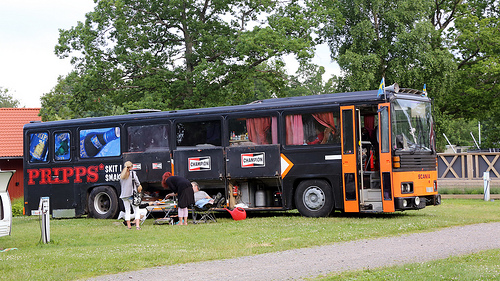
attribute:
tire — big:
[77, 179, 129, 224]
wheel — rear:
[87, 184, 119, 220]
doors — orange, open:
[339, 103, 393, 213]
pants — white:
[175, 205, 188, 217]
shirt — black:
[166, 173, 193, 194]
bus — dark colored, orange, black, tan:
[22, 82, 439, 218]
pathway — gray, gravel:
[74, 217, 499, 279]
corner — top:
[365, 90, 403, 127]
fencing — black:
[436, 150, 484, 197]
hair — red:
[159, 170, 172, 181]